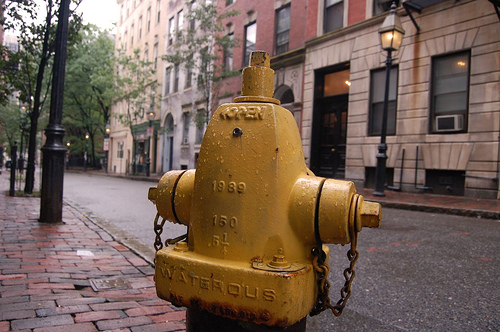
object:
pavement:
[2, 170, 499, 329]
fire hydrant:
[146, 48, 380, 332]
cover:
[86, 270, 133, 291]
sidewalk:
[0, 169, 188, 330]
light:
[345, 80, 352, 86]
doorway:
[158, 111, 179, 175]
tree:
[0, 1, 84, 194]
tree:
[1, 102, 26, 196]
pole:
[38, 0, 73, 224]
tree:
[114, 47, 163, 175]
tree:
[36, 23, 117, 166]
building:
[104, 0, 166, 175]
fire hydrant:
[112, 44, 397, 330]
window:
[425, 48, 471, 134]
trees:
[158, 1, 247, 141]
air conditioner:
[433, 114, 466, 133]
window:
[368, 63, 401, 136]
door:
[307, 59, 351, 180]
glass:
[320, 113, 344, 146]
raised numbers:
[212, 179, 246, 193]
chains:
[151, 212, 165, 266]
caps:
[145, 168, 196, 227]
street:
[34, 167, 499, 329]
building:
[302, 0, 499, 199]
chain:
[305, 241, 359, 318]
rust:
[154, 291, 296, 330]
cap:
[318, 178, 383, 247]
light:
[379, 0, 406, 50]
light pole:
[372, 50, 393, 197]